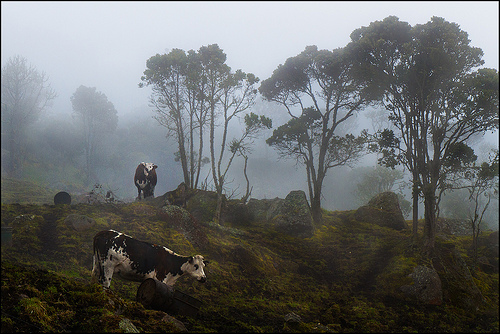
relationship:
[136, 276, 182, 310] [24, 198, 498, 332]
barrel sitting on hillside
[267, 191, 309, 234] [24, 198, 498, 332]
rock on hillside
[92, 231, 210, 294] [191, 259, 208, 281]
cow has face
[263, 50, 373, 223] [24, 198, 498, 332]
tree growing on hillside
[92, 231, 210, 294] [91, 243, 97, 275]
cow has tail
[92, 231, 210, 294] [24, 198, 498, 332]
cow standing on hillside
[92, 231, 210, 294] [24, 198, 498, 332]
cow facing down hillside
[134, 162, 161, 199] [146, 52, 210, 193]
cow standing next to tree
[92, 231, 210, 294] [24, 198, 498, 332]
cow facing bottom of hillside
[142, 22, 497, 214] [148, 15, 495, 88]
trees have leafy tops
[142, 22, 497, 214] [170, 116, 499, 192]
trees are bare on bottom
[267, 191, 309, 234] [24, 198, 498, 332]
rock lying on hillside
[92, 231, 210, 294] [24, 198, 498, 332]
cow walking down hillside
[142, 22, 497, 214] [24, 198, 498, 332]
trees are on top of hillside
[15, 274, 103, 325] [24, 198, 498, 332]
moss covering hillside